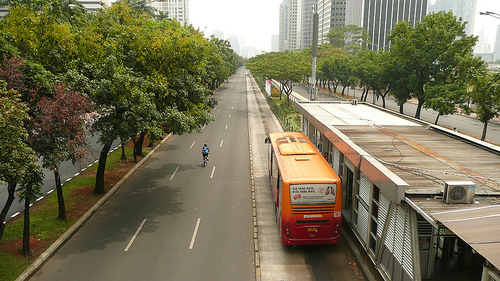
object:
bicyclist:
[202, 143, 211, 163]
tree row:
[1, 0, 248, 259]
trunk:
[288, 218, 337, 239]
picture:
[0, 0, 500, 281]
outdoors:
[0, 56, 303, 281]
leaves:
[393, 18, 412, 33]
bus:
[265, 132, 343, 248]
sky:
[190, 0, 280, 58]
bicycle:
[201, 150, 209, 167]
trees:
[242, 9, 500, 141]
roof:
[293, 99, 499, 204]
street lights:
[479, 10, 500, 19]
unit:
[442, 180, 476, 204]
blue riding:
[203, 148, 208, 153]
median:
[1, 130, 170, 280]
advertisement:
[290, 183, 337, 205]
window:
[331, 13, 335, 16]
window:
[336, 19, 339, 22]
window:
[331, 24, 335, 27]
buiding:
[271, 0, 477, 53]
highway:
[0, 66, 262, 281]